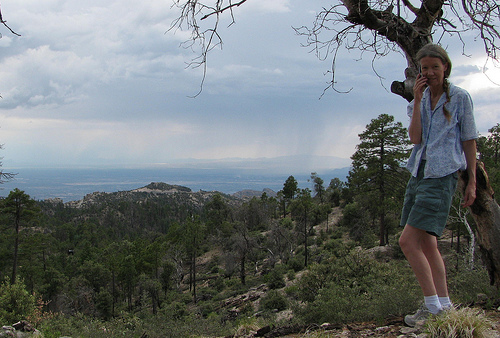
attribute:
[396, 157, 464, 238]
shorts — green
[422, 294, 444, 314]
sock — white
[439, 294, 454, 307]
sock — white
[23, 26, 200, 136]
clouds — heavy, rain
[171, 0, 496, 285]
tree — grey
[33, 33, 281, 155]
sky — grey and pink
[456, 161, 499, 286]
trunk — tree, brown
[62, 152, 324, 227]
hill — tall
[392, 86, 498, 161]
shirt — floral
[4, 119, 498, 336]
trees — green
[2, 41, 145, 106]
cloud — thick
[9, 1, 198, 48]
cloud — thick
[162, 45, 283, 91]
cloud — thick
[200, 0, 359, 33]
cloud — thick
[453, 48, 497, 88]
cloud — thick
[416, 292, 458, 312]
socks — white